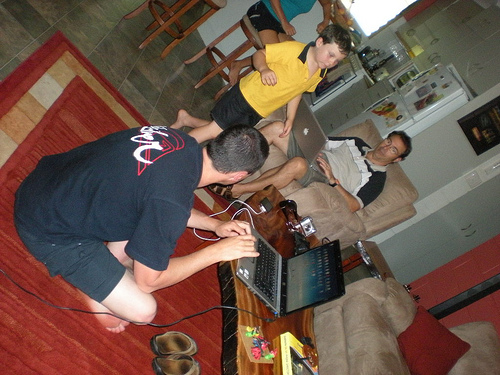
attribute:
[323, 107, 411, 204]
dad — seated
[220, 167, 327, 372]
coffee table — brown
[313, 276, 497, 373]
sofa — light brown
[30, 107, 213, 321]
outfit — black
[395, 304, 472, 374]
pillow — Red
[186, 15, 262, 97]
stool — wood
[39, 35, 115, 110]
rug — red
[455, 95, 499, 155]
frame — wooden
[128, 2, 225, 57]
chair — wooden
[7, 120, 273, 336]
guy — seated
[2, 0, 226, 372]
floor — red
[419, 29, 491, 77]
cabinet — white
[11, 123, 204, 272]
shirt — black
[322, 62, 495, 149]
appliance — White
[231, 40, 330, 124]
shirt — black, yellow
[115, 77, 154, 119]
tile — grey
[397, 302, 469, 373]
pillow — red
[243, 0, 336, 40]
mom — seated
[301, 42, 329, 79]
collar — black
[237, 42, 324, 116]
shirt — yellow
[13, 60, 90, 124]
carpet — red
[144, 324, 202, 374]
slippers — brown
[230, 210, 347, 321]
laptop — open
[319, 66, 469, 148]
refrigerator — white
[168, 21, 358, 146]
boy — yellow, black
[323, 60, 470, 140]
refrigerator — White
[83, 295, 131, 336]
foot — bare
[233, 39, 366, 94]
son — walking